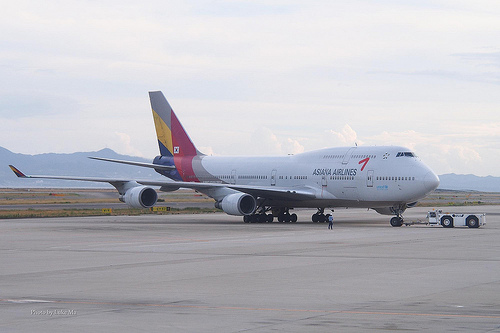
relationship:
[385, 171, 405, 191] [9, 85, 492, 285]
windows on a plane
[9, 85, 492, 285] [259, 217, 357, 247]
plane on ground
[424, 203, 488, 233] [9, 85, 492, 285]
truck towing plane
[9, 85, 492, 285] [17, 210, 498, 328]
plane on tarmack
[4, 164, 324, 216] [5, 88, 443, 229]
wing on a plane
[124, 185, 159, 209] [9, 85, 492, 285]
engine on a plane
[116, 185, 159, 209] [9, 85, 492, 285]
engine on a plane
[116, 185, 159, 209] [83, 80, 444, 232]
engine on a plane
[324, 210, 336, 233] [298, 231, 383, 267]
person is on runway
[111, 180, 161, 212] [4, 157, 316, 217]
engine is in right wing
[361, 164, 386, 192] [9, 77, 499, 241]
door is on plane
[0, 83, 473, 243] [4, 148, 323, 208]
airplane contains wing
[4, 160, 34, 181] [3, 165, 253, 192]
winglet on end of wing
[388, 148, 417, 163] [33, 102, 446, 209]
cockpit area on jet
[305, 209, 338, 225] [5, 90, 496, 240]
gear on airplane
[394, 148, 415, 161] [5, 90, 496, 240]
windshield on airplane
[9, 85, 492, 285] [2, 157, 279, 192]
plane has wing